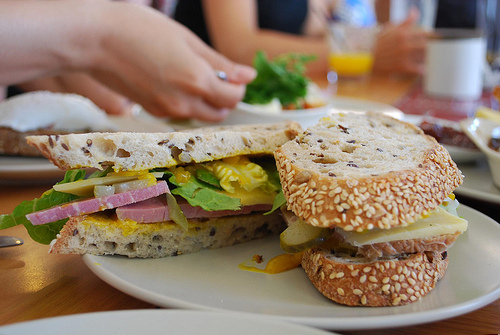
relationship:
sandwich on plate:
[19, 102, 475, 316] [71, 182, 498, 323]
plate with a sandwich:
[80, 193, 496, 330] [0, 118, 304, 261]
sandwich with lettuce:
[0, 118, 304, 261] [176, 162, 242, 215]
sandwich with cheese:
[0, 118, 304, 261] [338, 210, 466, 243]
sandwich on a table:
[0, 118, 304, 261] [4, 65, 499, 331]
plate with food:
[80, 203, 500, 334] [46, 210, 286, 261]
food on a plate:
[10, 97, 485, 311] [80, 193, 496, 330]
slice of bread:
[279, 111, 457, 230] [312, 208, 463, 310]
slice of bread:
[271, 111, 465, 234] [16, 115, 306, 172]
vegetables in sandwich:
[167, 156, 286, 213] [0, 118, 304, 261]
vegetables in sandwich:
[278, 215, 336, 254] [0, 118, 304, 261]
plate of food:
[80, 203, 500, 334] [46, 210, 286, 261]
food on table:
[46, 210, 286, 261] [2, 125, 497, 333]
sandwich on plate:
[0, 118, 304, 261] [80, 193, 496, 330]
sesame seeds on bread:
[275, 158, 458, 308] [23, 107, 464, 307]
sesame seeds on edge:
[275, 158, 458, 308] [281, 157, 458, 222]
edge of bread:
[281, 157, 458, 222] [23, 107, 464, 307]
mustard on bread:
[79, 212, 281, 256] [278, 105, 464, 234]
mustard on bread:
[79, 212, 281, 256] [297, 240, 450, 307]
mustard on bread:
[79, 212, 281, 256] [27, 117, 291, 177]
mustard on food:
[79, 212, 281, 256] [46, 210, 286, 261]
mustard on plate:
[82, 216, 182, 236] [93, 187, 470, 334]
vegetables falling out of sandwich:
[278, 215, 336, 254] [251, 120, 442, 300]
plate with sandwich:
[80, 203, 500, 334] [44, 83, 464, 303]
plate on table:
[80, 193, 496, 330] [4, 65, 499, 331]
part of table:
[7, 276, 51, 304] [4, 65, 499, 331]